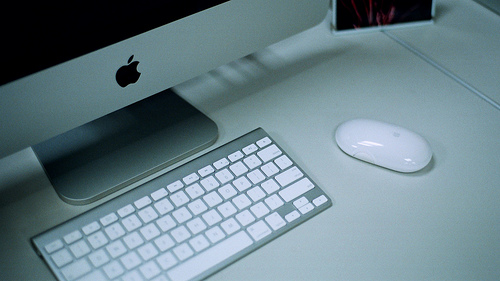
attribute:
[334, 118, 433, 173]
mouse — white, sleek, wireless, glossy, cordless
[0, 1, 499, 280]
desk — white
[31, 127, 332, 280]
keyboard — grey, brushed silver, silver, white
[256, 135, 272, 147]
button — white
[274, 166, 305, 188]
button — white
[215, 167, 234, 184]
button — white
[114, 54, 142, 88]
apple — logo, monitor, on monitor, black, setup, brand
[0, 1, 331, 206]
computer — apple brand, desktop, monitor, apple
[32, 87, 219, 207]
leg — silver, grey, gray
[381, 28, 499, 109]
cord — white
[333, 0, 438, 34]
card — black, in frame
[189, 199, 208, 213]
key — white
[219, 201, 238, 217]
key — white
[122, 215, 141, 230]
key — white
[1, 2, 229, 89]
screen — dark